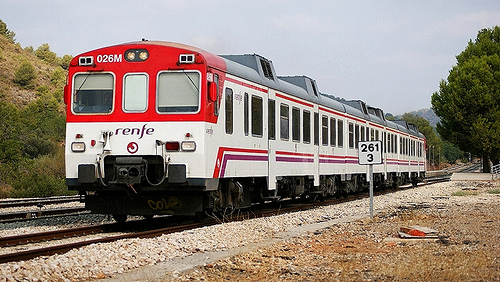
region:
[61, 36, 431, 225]
train on a track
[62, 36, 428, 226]
red and white train on a track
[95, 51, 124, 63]
white print on the front of a train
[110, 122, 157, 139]
burgundy print on the front of a train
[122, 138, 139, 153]
burgundy circular design on the front of a train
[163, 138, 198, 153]
red and white light on the front of a train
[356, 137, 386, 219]
white and black sign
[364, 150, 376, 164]
the number 3 printed on a sign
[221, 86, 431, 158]
row of windows on a train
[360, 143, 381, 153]
the number 261 printed on a sign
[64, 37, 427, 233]
A red and white train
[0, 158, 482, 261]
Some railroad tracks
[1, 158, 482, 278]
some gravel on the railroad tracks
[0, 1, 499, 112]
A cloudy sky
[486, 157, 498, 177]
some metal handrails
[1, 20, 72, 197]
A small grassy hill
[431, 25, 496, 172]
A large, full tree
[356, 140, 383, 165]
A white sign by the tracks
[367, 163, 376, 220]
A metal pole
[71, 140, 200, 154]
some headlights on the train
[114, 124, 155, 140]
the blue word renfe on the train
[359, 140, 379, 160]
a black and white sign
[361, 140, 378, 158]
the numbers on a sign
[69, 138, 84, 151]
the headlight of a train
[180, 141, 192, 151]
the headlight of a train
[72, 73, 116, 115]
the square window of a train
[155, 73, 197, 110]
the square window of a train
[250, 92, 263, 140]
the square window of a train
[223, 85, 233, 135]
the square window of a train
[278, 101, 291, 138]
the square window of a train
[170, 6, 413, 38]
the sky is gray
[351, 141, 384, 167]
the sign is white and black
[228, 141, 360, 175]
the stripes are red and purple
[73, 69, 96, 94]
the windshield has a wiper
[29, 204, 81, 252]
the track is brown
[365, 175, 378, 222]
the pole is silver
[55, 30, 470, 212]
the train is red and white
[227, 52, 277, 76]
the roof is gray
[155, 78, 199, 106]
the blinds are white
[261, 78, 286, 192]
the train has a door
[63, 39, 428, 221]
Train on train track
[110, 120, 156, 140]
renfe logo on train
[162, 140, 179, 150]
Red light next to white light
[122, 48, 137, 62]
Round yellow light is lit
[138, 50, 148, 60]
Round yellow light is lit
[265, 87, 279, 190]
White door on train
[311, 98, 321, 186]
White door on train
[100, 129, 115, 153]
White horn next to renfe logo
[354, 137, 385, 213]
Black and white train traffic sign next to train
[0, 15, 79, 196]
Green hill next to train